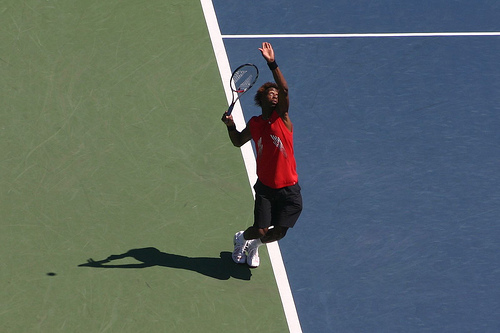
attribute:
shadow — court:
[80, 245, 251, 284]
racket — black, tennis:
[187, 52, 272, 127]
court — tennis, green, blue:
[7, 4, 498, 329]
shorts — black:
[242, 172, 310, 234]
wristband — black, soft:
[266, 57, 281, 68]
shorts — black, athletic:
[228, 165, 329, 234]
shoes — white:
[183, 204, 280, 270]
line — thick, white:
[205, 1, 262, 188]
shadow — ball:
[42, 268, 58, 276]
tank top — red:
[247, 115, 300, 187]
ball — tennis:
[38, 268, 108, 293]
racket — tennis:
[207, 58, 253, 135]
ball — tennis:
[44, 256, 93, 290]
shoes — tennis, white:
[224, 236, 270, 272]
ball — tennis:
[45, 257, 65, 287]